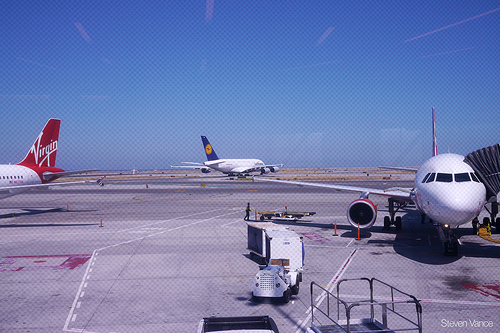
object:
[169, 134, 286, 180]
plane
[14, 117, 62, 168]
tail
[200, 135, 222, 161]
tail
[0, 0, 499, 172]
sky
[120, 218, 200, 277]
pavement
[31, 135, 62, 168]
logo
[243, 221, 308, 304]
cart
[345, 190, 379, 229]
engine